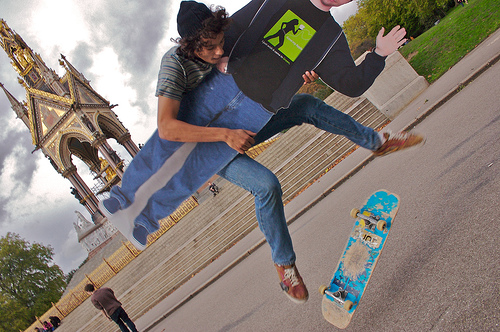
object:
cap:
[172, 0, 225, 38]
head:
[172, 0, 232, 65]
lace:
[284, 266, 305, 288]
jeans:
[110, 70, 274, 234]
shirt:
[153, 44, 218, 99]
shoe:
[276, 261, 314, 305]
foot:
[274, 261, 312, 303]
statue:
[97, 155, 116, 184]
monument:
[0, 18, 144, 254]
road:
[144, 55, 499, 331]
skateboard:
[319, 187, 404, 331]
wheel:
[347, 206, 361, 219]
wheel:
[373, 219, 389, 232]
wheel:
[340, 300, 353, 313]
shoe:
[375, 130, 430, 159]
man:
[84, 280, 139, 332]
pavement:
[113, 28, 500, 332]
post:
[33, 313, 47, 331]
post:
[83, 272, 102, 291]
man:
[153, 0, 428, 302]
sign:
[357, 229, 382, 248]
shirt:
[89, 285, 122, 316]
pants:
[106, 304, 142, 331]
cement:
[423, 235, 471, 290]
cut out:
[95, 0, 411, 253]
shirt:
[215, 0, 388, 117]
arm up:
[310, 23, 408, 99]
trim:
[356, 229, 382, 249]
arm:
[157, 45, 228, 143]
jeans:
[216, 91, 381, 266]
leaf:
[413, 7, 426, 21]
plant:
[340, 1, 464, 70]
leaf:
[384, 16, 389, 25]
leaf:
[18, 254, 28, 264]